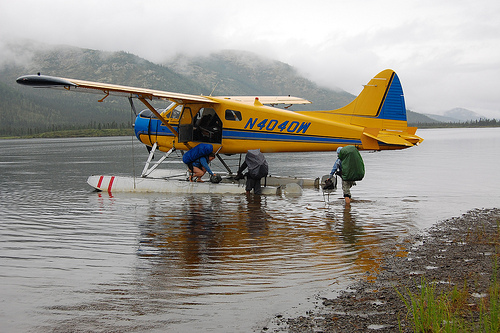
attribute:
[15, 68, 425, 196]
plane — water, orange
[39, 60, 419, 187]
plane — striped, blue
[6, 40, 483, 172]
mountains — black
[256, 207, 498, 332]
land — leaning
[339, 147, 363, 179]
pack — leaning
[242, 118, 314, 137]
text — blue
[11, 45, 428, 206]
plane — floating, yellow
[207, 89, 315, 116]
wing — yellow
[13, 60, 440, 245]
plane — leaning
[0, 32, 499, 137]
mountains — distant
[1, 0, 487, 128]
fog — low rolling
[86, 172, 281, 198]
pontoon — white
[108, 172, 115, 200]
stripe — red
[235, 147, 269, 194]
man — leaning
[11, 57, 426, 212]
yellow airplane — leaning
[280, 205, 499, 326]
shore — gravely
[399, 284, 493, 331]
grass — growing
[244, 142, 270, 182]
ruck sack — navy blue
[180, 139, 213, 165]
ruck sack — dark blue